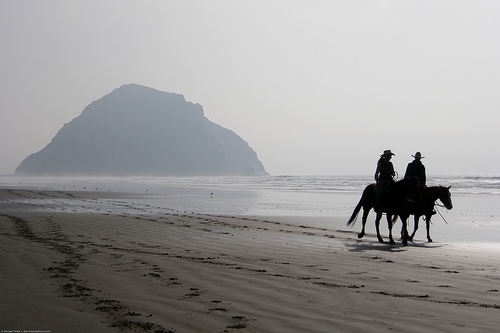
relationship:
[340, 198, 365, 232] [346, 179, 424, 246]
tail of horse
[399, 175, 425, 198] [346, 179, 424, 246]
head of horse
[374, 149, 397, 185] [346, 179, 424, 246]
lady on horse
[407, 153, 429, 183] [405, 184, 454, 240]
man on horse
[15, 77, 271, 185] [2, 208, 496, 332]
hill by beach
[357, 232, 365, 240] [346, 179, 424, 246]
hoof of horse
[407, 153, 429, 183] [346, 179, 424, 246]
man on horse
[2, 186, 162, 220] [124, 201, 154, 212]
sand has footprints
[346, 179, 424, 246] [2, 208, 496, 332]
horse walking beach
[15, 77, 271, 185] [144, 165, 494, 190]
hill next to water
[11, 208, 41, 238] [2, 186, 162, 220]
tracks on sand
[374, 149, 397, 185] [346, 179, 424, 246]
lady riding horse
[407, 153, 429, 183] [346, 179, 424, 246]
man riding horse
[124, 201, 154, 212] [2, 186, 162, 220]
footprints in sand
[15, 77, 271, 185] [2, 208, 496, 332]
hill near beach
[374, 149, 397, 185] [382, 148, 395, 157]
woman wearing hat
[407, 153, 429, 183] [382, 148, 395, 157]
man wearing hat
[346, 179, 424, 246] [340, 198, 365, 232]
horse has tail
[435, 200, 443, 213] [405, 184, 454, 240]
reins on horse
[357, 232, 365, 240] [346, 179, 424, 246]
hoof on horse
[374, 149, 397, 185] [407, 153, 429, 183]
lady and man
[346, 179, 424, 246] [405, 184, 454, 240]
horse and horse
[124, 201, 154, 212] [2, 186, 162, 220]
footprints on sand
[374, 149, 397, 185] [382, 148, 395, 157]
lady wearing hat